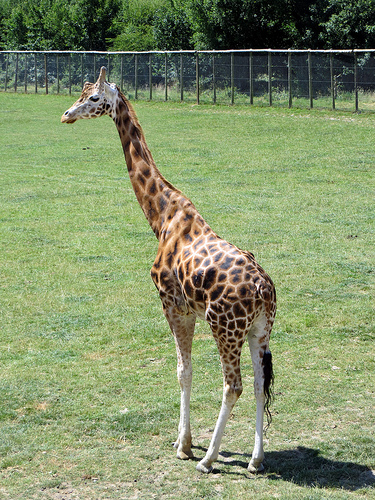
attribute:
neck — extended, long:
[121, 123, 181, 214]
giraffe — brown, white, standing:
[58, 66, 278, 475]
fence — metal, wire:
[9, 51, 374, 85]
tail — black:
[265, 339, 275, 428]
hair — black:
[262, 362, 274, 423]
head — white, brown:
[53, 78, 125, 120]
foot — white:
[174, 434, 193, 461]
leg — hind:
[194, 332, 241, 469]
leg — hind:
[247, 348, 277, 472]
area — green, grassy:
[9, 80, 365, 489]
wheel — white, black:
[8, 80, 32, 90]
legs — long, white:
[130, 337, 303, 457]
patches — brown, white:
[190, 268, 237, 299]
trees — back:
[9, 7, 341, 79]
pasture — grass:
[15, 91, 367, 494]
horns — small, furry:
[92, 62, 117, 76]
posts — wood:
[200, 64, 310, 84]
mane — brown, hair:
[138, 117, 167, 171]